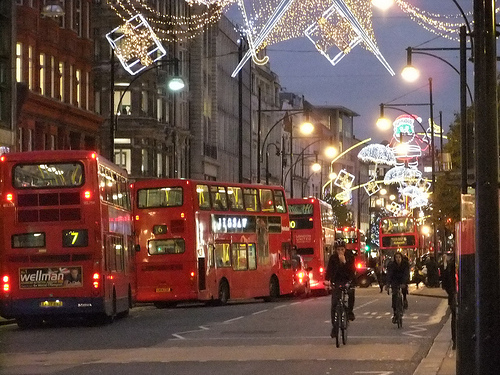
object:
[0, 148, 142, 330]
bus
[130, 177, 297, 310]
bus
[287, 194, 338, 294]
bus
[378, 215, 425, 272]
bus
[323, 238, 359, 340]
person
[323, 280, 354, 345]
bike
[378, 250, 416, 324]
person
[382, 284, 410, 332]
bicycle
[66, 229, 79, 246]
number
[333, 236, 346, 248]
helmet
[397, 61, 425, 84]
light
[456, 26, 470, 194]
pole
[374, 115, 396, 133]
light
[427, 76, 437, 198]
pole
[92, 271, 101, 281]
taillight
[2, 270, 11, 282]
taillight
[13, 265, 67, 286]
sign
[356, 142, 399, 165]
umbrella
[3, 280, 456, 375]
street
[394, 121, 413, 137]
face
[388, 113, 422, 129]
hat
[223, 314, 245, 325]
line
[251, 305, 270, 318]
line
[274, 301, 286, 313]
line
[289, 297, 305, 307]
line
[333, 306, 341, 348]
tire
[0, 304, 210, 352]
shadow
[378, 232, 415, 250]
sign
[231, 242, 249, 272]
window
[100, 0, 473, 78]
christmas-lights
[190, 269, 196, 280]
taillight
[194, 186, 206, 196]
light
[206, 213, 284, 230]
sign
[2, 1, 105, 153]
building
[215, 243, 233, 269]
window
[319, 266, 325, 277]
taillight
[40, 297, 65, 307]
plate